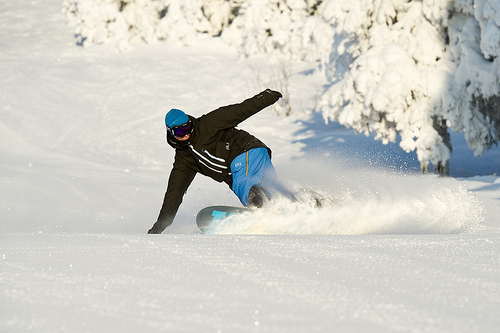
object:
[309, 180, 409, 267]
snow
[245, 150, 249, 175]
stripe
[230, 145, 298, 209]
pants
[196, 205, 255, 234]
board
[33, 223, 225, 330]
snow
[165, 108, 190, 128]
blue cap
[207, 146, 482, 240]
snow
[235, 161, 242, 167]
symbol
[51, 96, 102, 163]
snow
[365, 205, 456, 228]
snow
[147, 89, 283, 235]
black jacket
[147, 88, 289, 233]
man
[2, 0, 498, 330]
snow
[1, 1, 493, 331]
ground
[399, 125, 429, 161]
snow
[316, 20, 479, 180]
trees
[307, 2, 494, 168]
tree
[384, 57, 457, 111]
snow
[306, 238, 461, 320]
pepperoni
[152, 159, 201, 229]
arm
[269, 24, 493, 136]
trees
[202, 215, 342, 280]
snow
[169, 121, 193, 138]
goggles